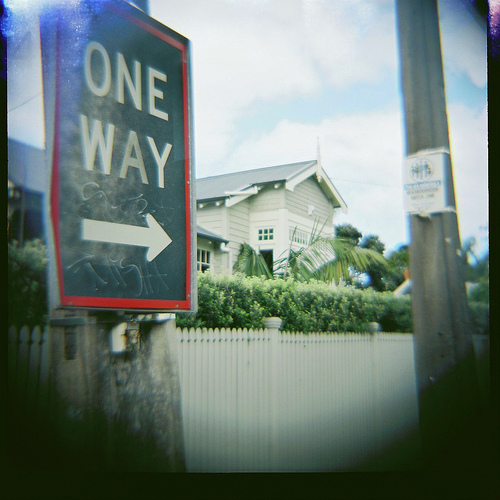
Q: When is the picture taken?
A: Daytime.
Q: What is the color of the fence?
A: White.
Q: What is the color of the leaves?
A: Green.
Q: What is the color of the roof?
A: Grey.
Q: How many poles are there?
A: Two.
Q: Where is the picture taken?
A: On the one way street.